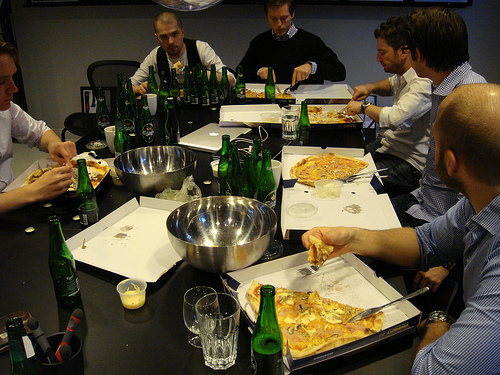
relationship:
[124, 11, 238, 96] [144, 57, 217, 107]
man wearing vest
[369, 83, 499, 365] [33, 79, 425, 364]
man eating pizza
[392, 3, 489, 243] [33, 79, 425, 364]
man eating pizza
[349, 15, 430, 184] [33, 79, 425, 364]
man eating pizza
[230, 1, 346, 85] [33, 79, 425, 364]
man eating pizza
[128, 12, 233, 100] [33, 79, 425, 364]
man eating pizza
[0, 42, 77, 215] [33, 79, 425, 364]
guy eating pizza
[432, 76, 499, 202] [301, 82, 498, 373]
head of man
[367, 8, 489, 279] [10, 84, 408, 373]
man sitting around a table